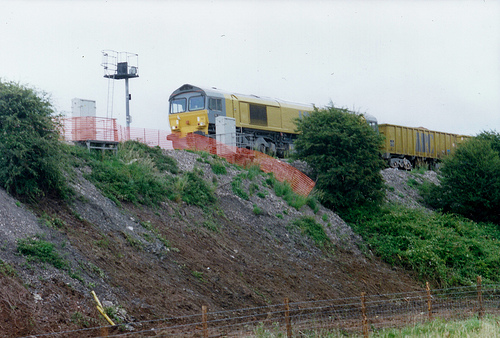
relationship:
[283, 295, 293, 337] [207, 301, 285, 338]
wood and wire.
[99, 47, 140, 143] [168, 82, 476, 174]
tower by train.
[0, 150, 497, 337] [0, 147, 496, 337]
dirt and rocks.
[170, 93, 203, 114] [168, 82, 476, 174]
windshield of train.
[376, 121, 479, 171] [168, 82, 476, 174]
car of train.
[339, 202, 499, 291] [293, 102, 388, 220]
weeds in bushes.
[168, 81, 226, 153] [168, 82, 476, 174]
front of train.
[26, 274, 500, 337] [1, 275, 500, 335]
fence at bottom.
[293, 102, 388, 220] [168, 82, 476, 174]
bush by train.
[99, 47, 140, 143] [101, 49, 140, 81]
stand on top.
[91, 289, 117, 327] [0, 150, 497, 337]
stick on ground.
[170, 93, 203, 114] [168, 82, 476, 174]
windoes on train.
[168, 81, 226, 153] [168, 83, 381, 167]
grey train car.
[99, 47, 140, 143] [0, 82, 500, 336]
tower in yard.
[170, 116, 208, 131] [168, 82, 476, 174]
headlights of train.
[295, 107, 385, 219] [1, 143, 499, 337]
tree on slope.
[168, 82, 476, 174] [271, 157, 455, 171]
train on tracks.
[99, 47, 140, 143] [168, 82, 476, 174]
tower behind train.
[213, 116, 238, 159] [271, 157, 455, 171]
container beside tracks.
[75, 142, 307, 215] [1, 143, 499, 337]
grass on hillside.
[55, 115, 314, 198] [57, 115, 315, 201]
fence hanging down.